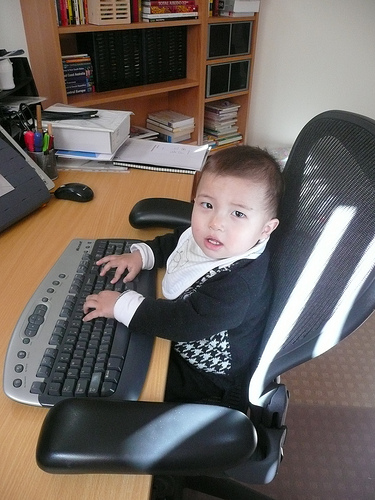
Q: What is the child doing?
A: The child is pretending to type.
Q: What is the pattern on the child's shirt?
A: The pattern is a houndstooth.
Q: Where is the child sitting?
A: The child is sitting in an office chair.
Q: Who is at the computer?
A: A child.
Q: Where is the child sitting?
A: At a desk.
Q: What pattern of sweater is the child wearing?
A: Herringbone.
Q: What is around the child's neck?
A: Bib.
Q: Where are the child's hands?
A: The keyboard.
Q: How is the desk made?
A: Of wood.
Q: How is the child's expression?
A: Perplexed.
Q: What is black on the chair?
A: Arm rests.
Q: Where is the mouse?
A: On the desk.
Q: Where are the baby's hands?
A: On keyboard.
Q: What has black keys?
A: The keyboard.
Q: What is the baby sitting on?
A: Chair.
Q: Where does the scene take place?
A: In an office.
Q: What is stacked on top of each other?
A: Books.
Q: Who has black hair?
A: The baby.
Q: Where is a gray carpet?
A: On the floor.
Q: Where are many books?
A: On a bookshelf.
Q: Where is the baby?
A: Desk.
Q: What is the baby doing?
A: Typing on keyboard.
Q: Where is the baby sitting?
A: On a chair.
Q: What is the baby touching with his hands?
A: A keyboard.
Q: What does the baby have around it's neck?
A: A bib.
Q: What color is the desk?
A: Brown.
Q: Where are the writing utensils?
A: On the desk.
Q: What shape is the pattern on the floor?
A: Square.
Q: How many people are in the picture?
A: One.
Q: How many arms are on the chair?
A: Two.